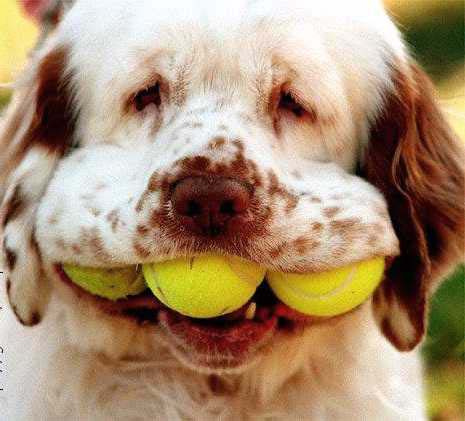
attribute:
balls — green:
[146, 226, 382, 330]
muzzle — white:
[258, 166, 400, 269]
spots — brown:
[284, 195, 380, 258]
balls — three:
[62, 247, 383, 297]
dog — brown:
[99, 63, 280, 265]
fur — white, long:
[238, 358, 307, 401]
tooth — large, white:
[243, 296, 263, 321]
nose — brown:
[166, 170, 251, 241]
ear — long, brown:
[352, 67, 464, 343]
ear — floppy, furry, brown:
[387, 56, 463, 349]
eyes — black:
[123, 75, 316, 126]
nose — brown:
[172, 157, 259, 236]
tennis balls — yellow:
[51, 248, 387, 328]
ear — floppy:
[0, 58, 54, 328]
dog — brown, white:
[0, 0, 463, 419]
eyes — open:
[125, 79, 322, 118]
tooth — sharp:
[242, 301, 257, 320]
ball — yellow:
[141, 251, 266, 318]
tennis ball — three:
[266, 252, 384, 317]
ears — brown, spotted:
[8, 47, 130, 289]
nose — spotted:
[163, 166, 258, 236]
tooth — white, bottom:
[247, 288, 262, 332]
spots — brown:
[30, 110, 411, 272]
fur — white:
[320, 10, 370, 53]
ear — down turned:
[0, 20, 76, 327]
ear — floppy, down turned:
[359, 56, 463, 351]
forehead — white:
[111, 5, 325, 90]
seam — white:
[272, 269, 370, 299]